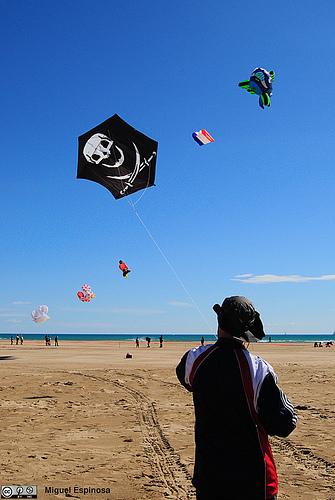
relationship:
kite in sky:
[236, 64, 278, 111] [0, 0, 334, 335]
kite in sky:
[189, 125, 215, 148] [0, 0, 334, 335]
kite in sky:
[73, 110, 161, 202] [0, 0, 334, 335]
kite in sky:
[114, 253, 132, 278] [0, 0, 334, 335]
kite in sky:
[75, 281, 97, 302] [0, 0, 334, 335]